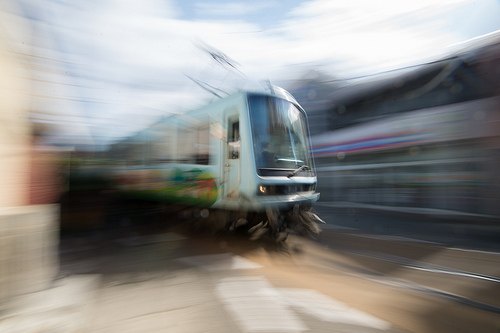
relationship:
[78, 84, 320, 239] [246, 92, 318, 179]
train has windshield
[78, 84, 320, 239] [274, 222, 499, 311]
train riding on tracks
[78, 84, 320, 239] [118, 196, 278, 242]
train has wheels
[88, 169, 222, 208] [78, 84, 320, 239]
logo on side of train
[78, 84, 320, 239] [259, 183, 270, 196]
train has headlight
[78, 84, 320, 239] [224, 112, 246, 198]
train has door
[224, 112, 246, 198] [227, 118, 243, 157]
door has window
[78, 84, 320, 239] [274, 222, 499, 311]
train behind tracks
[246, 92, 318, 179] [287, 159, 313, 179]
windshield has wiper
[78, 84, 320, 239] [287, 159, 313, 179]
train has wiper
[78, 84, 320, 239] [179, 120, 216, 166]
train has window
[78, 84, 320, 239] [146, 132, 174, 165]
train has window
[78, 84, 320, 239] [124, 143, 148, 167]
train has window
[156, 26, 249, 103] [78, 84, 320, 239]
wires above train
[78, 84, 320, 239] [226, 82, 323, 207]
train has front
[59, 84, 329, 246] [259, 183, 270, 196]
train has headlight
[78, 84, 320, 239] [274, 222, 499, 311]
train on top of tracks